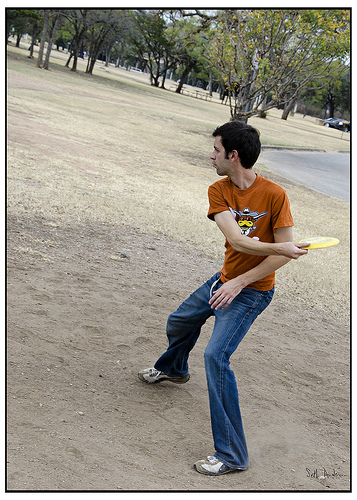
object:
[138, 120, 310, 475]
man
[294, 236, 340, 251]
frisbee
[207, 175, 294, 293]
shirt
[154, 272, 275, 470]
jeans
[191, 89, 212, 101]
picnic table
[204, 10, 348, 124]
tree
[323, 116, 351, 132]
car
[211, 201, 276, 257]
arm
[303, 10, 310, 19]
leaf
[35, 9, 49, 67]
trunk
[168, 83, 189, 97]
picnic bench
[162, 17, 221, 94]
tree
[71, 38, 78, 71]
trunk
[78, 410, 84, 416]
rock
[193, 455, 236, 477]
sneaker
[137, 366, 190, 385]
shoe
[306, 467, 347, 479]
name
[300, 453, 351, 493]
corner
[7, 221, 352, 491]
sand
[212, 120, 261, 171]
hair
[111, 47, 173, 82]
building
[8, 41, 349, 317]
grass